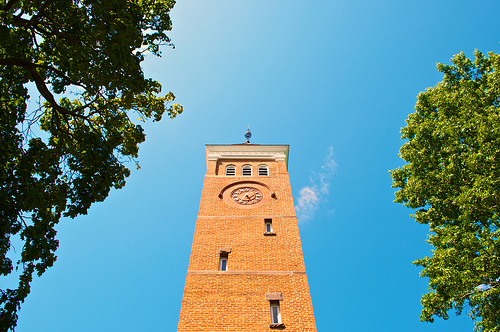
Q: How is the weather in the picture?
A: It is clear.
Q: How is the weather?
A: It is clear.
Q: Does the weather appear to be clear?
A: Yes, it is clear.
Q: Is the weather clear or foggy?
A: It is clear.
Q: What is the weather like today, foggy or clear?
A: It is clear.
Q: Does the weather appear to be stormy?
A: No, it is clear.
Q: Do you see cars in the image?
A: No, there are no cars.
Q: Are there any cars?
A: No, there are no cars.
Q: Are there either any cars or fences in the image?
A: No, there are no cars or fences.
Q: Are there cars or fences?
A: No, there are no cars or fences.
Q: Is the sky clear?
A: Yes, the sky is clear.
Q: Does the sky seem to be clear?
A: Yes, the sky is clear.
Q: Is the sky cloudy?
A: No, the sky is clear.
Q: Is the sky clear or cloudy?
A: The sky is clear.